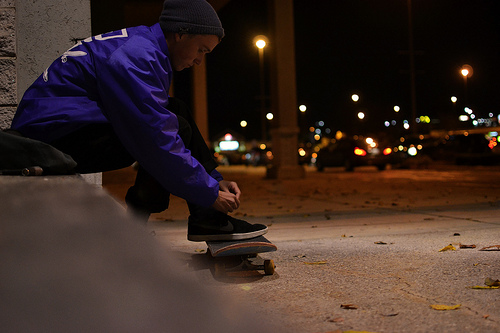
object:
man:
[10, 0, 269, 241]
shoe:
[186, 212, 269, 243]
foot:
[186, 208, 269, 243]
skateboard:
[203, 234, 277, 278]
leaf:
[476, 240, 499, 252]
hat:
[156, 0, 226, 40]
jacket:
[8, 21, 225, 209]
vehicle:
[314, 132, 395, 173]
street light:
[250, 34, 269, 138]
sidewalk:
[104, 168, 499, 332]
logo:
[191, 218, 235, 232]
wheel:
[211, 260, 227, 279]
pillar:
[261, 1, 307, 183]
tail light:
[353, 144, 368, 158]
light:
[251, 33, 270, 53]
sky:
[91, 1, 499, 136]